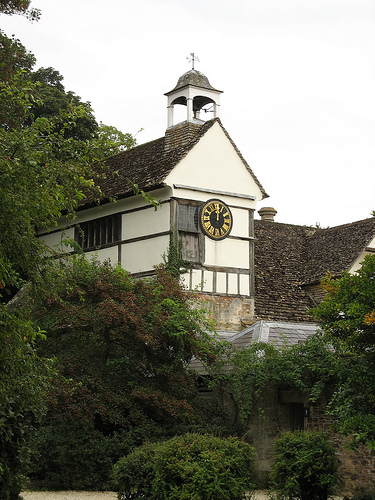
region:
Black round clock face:
[197, 197, 239, 242]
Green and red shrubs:
[59, 271, 182, 438]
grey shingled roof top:
[245, 315, 314, 343]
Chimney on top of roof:
[258, 204, 277, 223]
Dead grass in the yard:
[27, 487, 97, 499]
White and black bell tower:
[158, 46, 220, 129]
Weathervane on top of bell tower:
[180, 47, 203, 68]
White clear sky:
[263, 36, 350, 165]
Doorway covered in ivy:
[277, 392, 316, 452]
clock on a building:
[197, 193, 239, 243]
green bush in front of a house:
[111, 423, 247, 499]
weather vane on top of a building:
[172, 42, 212, 72]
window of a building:
[168, 191, 202, 275]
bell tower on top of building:
[161, 66, 221, 127]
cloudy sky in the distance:
[259, 26, 347, 163]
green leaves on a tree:
[1, 51, 124, 251]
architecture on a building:
[179, 261, 248, 294]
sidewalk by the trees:
[24, 483, 120, 498]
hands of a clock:
[208, 205, 226, 227]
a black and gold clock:
[200, 198, 233, 239]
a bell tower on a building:
[166, 67, 220, 147]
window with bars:
[69, 214, 118, 254]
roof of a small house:
[197, 317, 343, 378]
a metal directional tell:
[186, 48, 202, 71]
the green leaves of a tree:
[284, 252, 374, 450]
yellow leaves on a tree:
[360, 307, 373, 328]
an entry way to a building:
[288, 399, 305, 431]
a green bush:
[111, 428, 258, 498]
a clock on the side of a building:
[198, 195, 233, 243]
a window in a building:
[173, 200, 204, 265]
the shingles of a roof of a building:
[270, 323, 304, 350]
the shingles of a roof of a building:
[263, 280, 296, 314]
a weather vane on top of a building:
[184, 48, 202, 73]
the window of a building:
[67, 212, 126, 253]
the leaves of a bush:
[142, 448, 216, 493]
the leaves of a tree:
[8, 98, 65, 167]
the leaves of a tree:
[96, 301, 152, 356]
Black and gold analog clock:
[199, 195, 233, 241]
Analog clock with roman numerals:
[199, 198, 233, 241]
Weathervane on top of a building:
[184, 50, 200, 70]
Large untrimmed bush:
[110, 431, 258, 497]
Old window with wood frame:
[169, 196, 205, 268]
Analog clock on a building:
[197, 197, 233, 240]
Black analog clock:
[197, 198, 233, 241]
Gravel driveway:
[17, 485, 364, 498]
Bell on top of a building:
[163, 67, 221, 129]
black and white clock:
[196, 192, 243, 243]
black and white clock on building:
[194, 193, 237, 248]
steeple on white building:
[150, 40, 246, 136]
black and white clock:
[194, 190, 235, 241]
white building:
[130, 111, 270, 311]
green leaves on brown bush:
[150, 454, 190, 481]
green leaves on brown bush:
[204, 446, 242, 471]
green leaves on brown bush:
[297, 451, 319, 478]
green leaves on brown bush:
[12, 403, 43, 429]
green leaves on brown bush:
[75, 445, 111, 470]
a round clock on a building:
[197, 195, 236, 241]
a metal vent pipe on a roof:
[257, 204, 277, 224]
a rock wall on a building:
[304, 390, 373, 486]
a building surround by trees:
[138, 321, 371, 490]